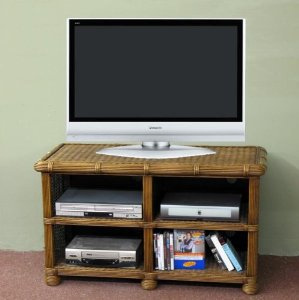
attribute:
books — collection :
[153, 229, 246, 277]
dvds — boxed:
[162, 228, 249, 279]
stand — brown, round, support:
[45, 275, 62, 290]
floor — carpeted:
[2, 252, 298, 298]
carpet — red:
[258, 255, 298, 295]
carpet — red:
[1, 250, 51, 297]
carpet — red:
[42, 286, 236, 299]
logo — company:
[148, 123, 168, 134]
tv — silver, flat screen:
[53, 17, 252, 170]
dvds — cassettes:
[150, 223, 254, 285]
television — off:
[66, 17, 247, 158]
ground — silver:
[222, 60, 245, 99]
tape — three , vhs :
[221, 238, 241, 270]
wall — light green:
[7, 6, 34, 207]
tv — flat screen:
[58, 15, 253, 142]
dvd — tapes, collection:
[170, 233, 177, 272]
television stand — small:
[28, 143, 268, 297]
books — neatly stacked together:
[152, 230, 173, 276]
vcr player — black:
[63, 231, 145, 272]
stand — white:
[95, 140, 216, 157]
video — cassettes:
[196, 234, 240, 280]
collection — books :
[147, 234, 235, 278]